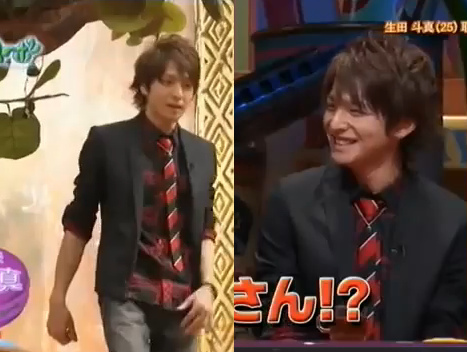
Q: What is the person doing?
A: Walking.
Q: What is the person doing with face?
A: Smiling.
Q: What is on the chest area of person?
A: Navy blue fitting blazer.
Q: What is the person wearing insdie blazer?
A: Red and black shirt.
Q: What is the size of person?
A: Slim.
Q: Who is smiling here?
A: The male person.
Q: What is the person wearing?
A: Red and black shirt.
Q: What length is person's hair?
A: Long.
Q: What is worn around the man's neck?
A: Tie.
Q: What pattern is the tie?
A: Stripes.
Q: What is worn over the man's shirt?
A: Jacket.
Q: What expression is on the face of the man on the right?
A: Smile.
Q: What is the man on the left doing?
A: Walking.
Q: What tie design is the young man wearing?
A: Red, black and white.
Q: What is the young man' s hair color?
A: Black.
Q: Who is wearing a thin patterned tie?
A: A young man.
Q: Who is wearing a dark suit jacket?
A: A young man.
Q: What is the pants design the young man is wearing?
A: Dark jeans.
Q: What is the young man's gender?
A: Male.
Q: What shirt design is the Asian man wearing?
A: Red and black.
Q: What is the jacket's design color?
A: Dark.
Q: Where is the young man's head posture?
A: Turned on the side.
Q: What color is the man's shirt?
A: Black.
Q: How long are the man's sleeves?
A: Up to his elbows.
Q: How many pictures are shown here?
A: Two.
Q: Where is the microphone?
A: On the lapel.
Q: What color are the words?
A: Orange.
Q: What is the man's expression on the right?
A: He's smiling.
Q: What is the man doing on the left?
A: Walking.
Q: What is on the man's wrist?
A: A bracelet.